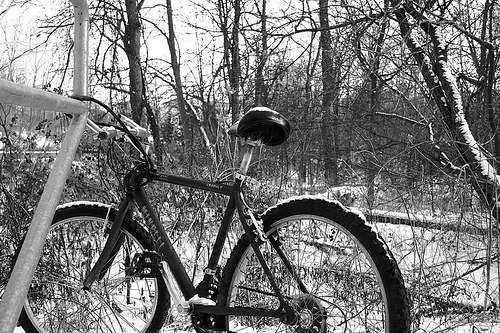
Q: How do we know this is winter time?
A: Snow is visible and the trees are bare.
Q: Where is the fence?
A: Behind the bicycle.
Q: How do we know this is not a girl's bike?
A: The three bar arrangement, between the seat and the handle bars.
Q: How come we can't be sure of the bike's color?
A: The picture is black and white.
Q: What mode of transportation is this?
A: A bike.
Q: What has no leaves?
A: Trees.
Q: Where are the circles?
A: On the bike.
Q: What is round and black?
A: Tires.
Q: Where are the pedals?
A: On the bike.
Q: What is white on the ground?
A: Snow.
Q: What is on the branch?
A: Snow.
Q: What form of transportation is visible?
A: Bicycle.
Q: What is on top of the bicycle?
A: Snow.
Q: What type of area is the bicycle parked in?
A: Woods.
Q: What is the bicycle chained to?
A: Metal bar.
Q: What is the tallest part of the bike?
A: Seat.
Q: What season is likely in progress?
A: Winter.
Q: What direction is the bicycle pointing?
A: Left.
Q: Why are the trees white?
A: Snow.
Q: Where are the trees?
A: Behind the bike.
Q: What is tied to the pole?
A: Bicycle.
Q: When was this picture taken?
A: Wintertime.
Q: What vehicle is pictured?
A: Bicycle.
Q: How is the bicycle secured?
A: Cable around metal pipe.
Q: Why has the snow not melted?
A: It is cold.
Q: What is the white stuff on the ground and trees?
A: Snow.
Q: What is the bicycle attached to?
A: Framework of metal pipe.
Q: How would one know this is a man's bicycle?
A: Straight crosspiece in frame.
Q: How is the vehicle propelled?
A: Pedaled by person.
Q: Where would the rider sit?
A: Bicycle seat.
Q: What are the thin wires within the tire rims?
A: Spokes.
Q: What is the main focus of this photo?
A: A bicycle.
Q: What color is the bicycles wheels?
A: Black.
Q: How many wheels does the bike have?
A: Two.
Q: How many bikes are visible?
A: One.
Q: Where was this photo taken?
A: Outside, in the snow.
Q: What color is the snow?
A: White.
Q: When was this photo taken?
A: During the winter months.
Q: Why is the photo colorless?
A: Black and white filter.